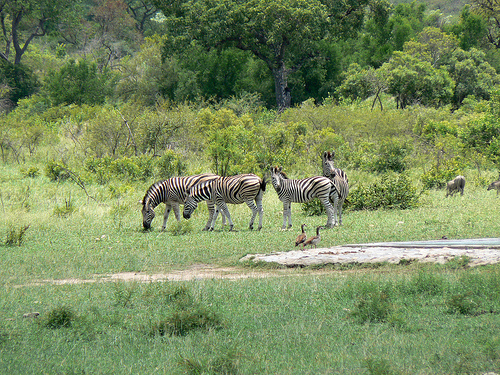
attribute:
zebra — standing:
[314, 146, 357, 232]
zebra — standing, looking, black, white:
[269, 156, 348, 234]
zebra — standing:
[175, 171, 271, 236]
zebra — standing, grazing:
[135, 171, 224, 236]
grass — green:
[0, 163, 499, 374]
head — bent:
[136, 201, 160, 236]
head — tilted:
[265, 164, 291, 197]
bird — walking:
[291, 218, 311, 253]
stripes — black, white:
[210, 179, 248, 198]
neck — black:
[298, 226, 307, 236]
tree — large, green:
[161, 0, 376, 115]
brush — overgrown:
[1, 1, 498, 184]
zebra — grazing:
[434, 170, 471, 200]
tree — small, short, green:
[371, 22, 500, 114]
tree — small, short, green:
[194, 105, 258, 179]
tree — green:
[5, 2, 61, 99]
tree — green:
[120, 2, 169, 46]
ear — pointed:
[317, 151, 328, 162]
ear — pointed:
[328, 151, 340, 162]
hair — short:
[141, 172, 169, 212]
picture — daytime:
[1, 1, 500, 371]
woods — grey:
[2, 1, 500, 104]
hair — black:
[334, 195, 347, 203]